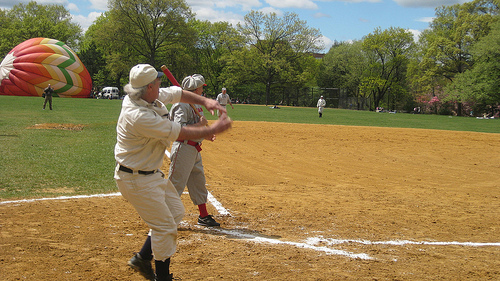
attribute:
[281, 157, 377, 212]
dirt — brown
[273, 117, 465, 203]
field — brown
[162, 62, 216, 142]
bat — red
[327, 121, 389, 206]
dirt — brown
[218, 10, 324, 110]
tree — large, green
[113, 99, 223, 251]
uniforms — replica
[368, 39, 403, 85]
tree — green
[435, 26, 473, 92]
tree — green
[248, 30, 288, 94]
tree — green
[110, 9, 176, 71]
tree — green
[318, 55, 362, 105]
tree — green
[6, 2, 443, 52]
sky — cloudy, blue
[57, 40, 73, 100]
stripe — green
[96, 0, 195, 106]
tree — green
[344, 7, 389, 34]
sky —  blue, cloudy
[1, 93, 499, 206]
grass — green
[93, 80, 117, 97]
van — white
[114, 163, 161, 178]
belt — black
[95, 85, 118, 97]
van — white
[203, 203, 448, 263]
chalk line — white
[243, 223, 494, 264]
lines — white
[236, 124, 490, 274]
dirt — brown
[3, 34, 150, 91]
balloon — hot air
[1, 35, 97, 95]
air balloon — large, hot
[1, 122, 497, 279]
field — dirt, baseball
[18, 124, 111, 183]
grass — green